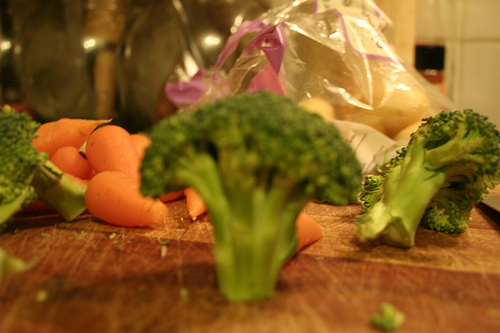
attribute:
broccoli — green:
[138, 88, 368, 304]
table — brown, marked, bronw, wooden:
[0, 197, 498, 331]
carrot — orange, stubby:
[85, 169, 171, 228]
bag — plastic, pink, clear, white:
[162, 1, 460, 131]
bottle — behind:
[414, 41, 447, 98]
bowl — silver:
[115, 0, 212, 120]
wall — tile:
[418, 4, 499, 131]